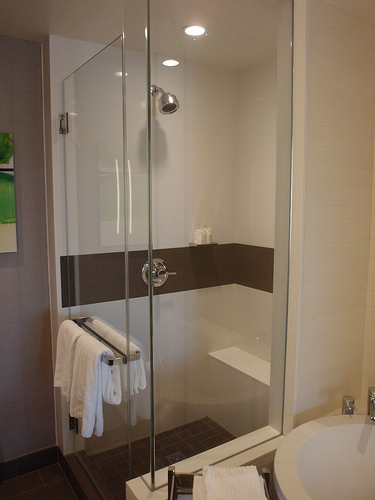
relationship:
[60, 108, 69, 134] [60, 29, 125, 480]
hinge on panel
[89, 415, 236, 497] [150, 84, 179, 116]
tile inside fixture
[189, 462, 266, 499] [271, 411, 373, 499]
towel beside sink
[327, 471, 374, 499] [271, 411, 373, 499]
basin of sink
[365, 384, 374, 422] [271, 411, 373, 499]
faucet over sink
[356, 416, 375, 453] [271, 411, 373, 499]
shadow on sink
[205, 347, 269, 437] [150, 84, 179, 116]
seat in fixture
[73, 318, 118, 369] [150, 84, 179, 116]
handle of fixture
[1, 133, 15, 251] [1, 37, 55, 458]
picture on wall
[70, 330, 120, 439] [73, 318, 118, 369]
towel on handle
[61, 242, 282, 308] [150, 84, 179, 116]
stripe in fixture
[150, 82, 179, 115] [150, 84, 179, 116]
fixture in fixture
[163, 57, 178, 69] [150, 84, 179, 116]
light in fixture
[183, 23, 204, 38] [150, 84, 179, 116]
light in fixture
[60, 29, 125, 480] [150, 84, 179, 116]
panel for fixture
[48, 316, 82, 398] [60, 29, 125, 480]
towel on panel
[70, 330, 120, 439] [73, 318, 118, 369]
towel hanging on handle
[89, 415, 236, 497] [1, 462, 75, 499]
tile on floor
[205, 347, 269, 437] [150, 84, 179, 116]
seat inside of fixture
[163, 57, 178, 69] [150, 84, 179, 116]
light inside of fixture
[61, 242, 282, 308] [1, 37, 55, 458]
stripe on wall